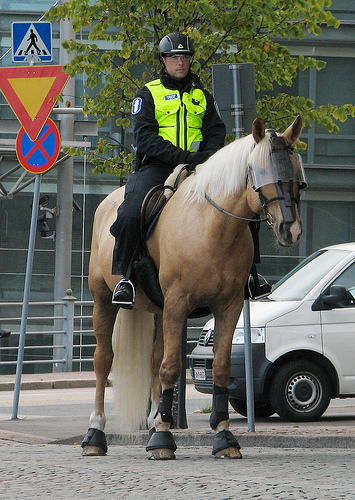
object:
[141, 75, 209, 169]
vest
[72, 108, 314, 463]
horse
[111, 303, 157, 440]
tail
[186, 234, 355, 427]
van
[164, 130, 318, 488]
front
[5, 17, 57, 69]
sign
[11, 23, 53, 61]
pedestrian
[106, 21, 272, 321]
man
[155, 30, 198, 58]
helmet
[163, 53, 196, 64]
glasses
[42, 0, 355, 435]
tree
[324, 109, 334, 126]
leaves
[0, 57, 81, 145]
sign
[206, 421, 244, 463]
foot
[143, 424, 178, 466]
foot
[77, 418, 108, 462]
foot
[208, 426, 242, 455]
hoof cover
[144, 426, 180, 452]
hoof cover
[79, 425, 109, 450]
hoof cover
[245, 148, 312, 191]
visor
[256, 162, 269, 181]
eyes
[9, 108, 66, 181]
sign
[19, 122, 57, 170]
x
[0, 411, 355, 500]
road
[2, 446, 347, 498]
bricks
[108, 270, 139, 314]
foot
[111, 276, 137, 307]
stirrup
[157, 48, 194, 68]
safety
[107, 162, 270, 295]
pants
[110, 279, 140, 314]
shoes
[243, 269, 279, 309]
shoes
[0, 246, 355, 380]
fence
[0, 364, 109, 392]
sidewalk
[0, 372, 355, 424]
street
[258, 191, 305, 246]
wraps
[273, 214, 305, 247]
shin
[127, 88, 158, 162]
sleeve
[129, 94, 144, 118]
patch